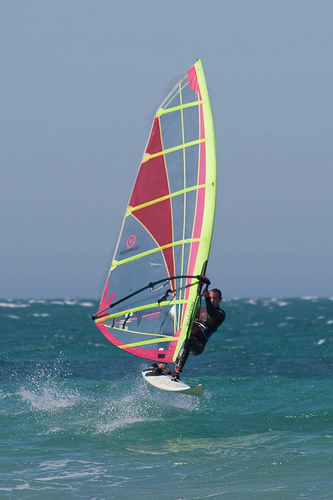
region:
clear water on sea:
[217, 419, 241, 464]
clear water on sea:
[242, 389, 280, 437]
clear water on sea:
[222, 431, 276, 479]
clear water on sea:
[141, 448, 169, 466]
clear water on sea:
[254, 381, 309, 478]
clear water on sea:
[234, 394, 292, 463]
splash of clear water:
[44, 357, 120, 429]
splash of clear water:
[39, 376, 113, 452]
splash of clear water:
[54, 384, 133, 477]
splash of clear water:
[14, 369, 135, 499]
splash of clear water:
[21, 339, 99, 432]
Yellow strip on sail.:
[147, 143, 221, 165]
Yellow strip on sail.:
[143, 174, 187, 216]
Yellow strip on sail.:
[95, 301, 189, 339]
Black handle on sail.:
[113, 281, 174, 319]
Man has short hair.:
[208, 283, 227, 303]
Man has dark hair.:
[210, 284, 225, 299]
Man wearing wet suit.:
[199, 299, 229, 375]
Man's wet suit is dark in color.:
[196, 302, 217, 380]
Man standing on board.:
[155, 357, 205, 393]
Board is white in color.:
[140, 355, 223, 424]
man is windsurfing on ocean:
[92, 57, 227, 392]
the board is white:
[139, 364, 205, 403]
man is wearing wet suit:
[148, 297, 225, 370]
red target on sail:
[125, 232, 136, 249]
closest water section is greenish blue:
[0, 379, 332, 498]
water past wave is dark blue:
[0, 298, 331, 379]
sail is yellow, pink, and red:
[92, 59, 216, 362]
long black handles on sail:
[84, 275, 209, 321]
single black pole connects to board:
[172, 280, 202, 388]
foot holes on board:
[143, 366, 168, 377]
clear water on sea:
[232, 370, 280, 428]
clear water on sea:
[222, 347, 310, 483]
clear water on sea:
[260, 411, 309, 463]